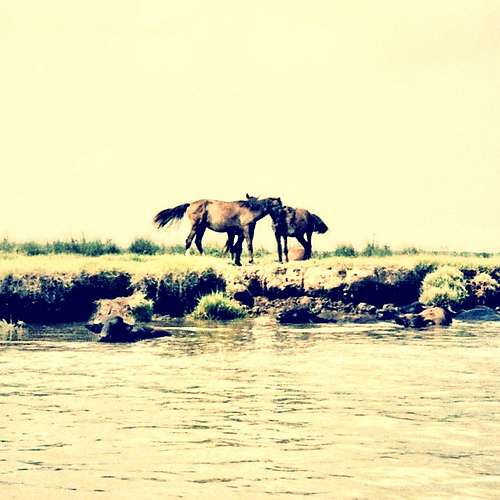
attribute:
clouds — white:
[130, 58, 252, 147]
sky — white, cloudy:
[5, 1, 497, 249]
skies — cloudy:
[72, 44, 270, 138]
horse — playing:
[159, 193, 279, 259]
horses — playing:
[150, 192, 333, 262]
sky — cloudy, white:
[372, 88, 498, 220]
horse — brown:
[171, 194, 328, 274]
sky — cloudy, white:
[351, 82, 454, 121]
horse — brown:
[260, 190, 336, 260]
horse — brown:
[146, 182, 288, 261]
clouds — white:
[223, 36, 478, 152]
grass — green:
[2, 240, 498, 270]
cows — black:
[83, 302, 341, 349]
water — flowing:
[240, 339, 369, 435]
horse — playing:
[264, 196, 329, 260]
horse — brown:
[263, 199, 326, 261]